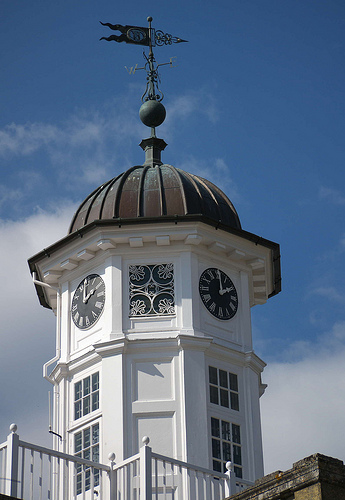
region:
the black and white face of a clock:
[69, 276, 104, 329]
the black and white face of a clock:
[198, 265, 235, 317]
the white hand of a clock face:
[81, 277, 87, 301]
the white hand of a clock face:
[82, 287, 95, 301]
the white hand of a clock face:
[216, 268, 222, 294]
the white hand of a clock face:
[220, 285, 231, 296]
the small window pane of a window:
[74, 381, 81, 398]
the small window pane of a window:
[81, 375, 90, 393]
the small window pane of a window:
[91, 372, 100, 391]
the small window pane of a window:
[210, 416, 219, 437]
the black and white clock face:
[69, 273, 102, 326]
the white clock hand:
[81, 276, 89, 301]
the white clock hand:
[82, 287, 95, 301]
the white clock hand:
[216, 269, 223, 292]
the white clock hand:
[220, 283, 232, 293]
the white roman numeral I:
[89, 274, 97, 285]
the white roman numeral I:
[222, 274, 228, 284]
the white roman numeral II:
[93, 281, 102, 290]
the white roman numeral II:
[226, 283, 232, 291]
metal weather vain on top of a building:
[93, 13, 189, 102]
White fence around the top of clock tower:
[2, 423, 161, 496]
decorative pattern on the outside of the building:
[125, 259, 178, 319]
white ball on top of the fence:
[138, 434, 152, 445]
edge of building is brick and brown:
[241, 453, 339, 497]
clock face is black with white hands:
[197, 265, 240, 321]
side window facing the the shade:
[195, 354, 250, 474]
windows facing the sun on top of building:
[62, 366, 105, 493]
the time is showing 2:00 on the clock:
[79, 274, 106, 303]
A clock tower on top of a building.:
[26, 137, 279, 499]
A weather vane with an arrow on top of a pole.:
[100, 15, 187, 136]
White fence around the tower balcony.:
[0, 423, 257, 498]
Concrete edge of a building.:
[224, 452, 344, 498]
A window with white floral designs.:
[129, 264, 173, 317]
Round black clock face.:
[68, 273, 104, 329]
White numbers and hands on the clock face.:
[69, 273, 104, 331]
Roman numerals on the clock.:
[70, 275, 105, 330]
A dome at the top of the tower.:
[62, 164, 238, 233]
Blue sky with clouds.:
[0, 0, 344, 498]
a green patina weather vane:
[97, 15, 191, 136]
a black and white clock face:
[200, 264, 237, 321]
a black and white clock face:
[70, 273, 104, 329]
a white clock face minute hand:
[216, 268, 222, 292]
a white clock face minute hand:
[80, 276, 83, 300]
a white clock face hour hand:
[217, 285, 230, 292]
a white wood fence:
[0, 423, 253, 498]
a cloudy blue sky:
[0, 0, 344, 496]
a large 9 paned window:
[67, 416, 101, 494]